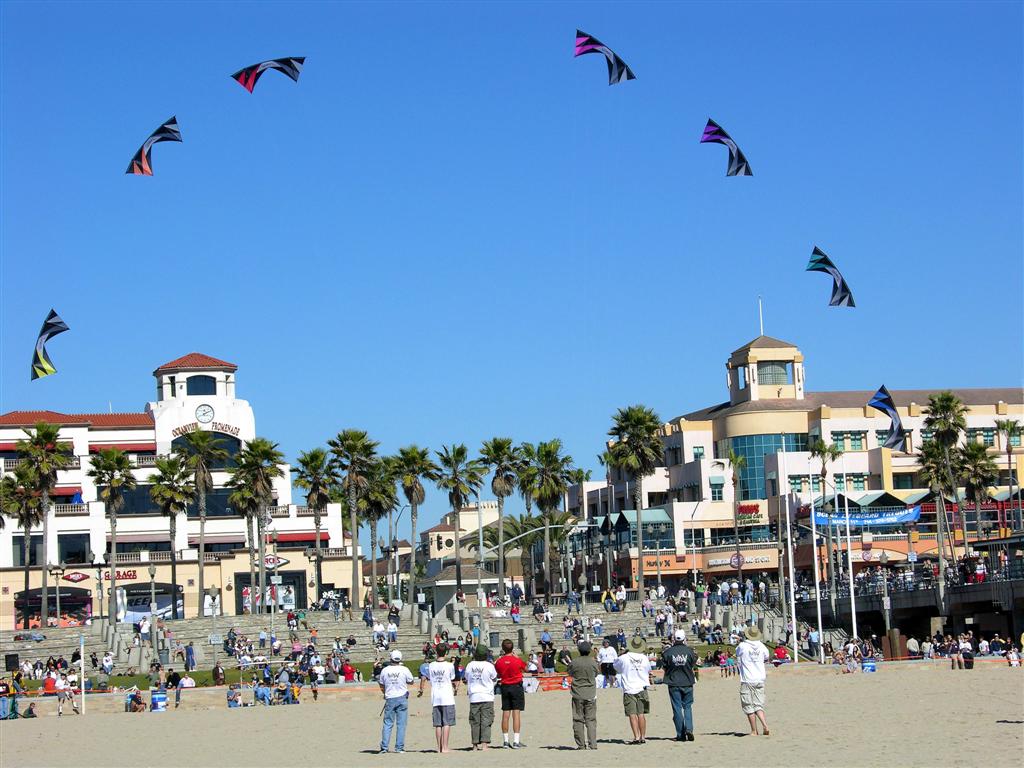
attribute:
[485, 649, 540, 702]
shirt — red 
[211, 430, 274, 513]
tree — green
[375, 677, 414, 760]
pants — light blue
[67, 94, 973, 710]
show — kite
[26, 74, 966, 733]
show — kite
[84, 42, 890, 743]
show — kite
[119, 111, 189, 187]
kite — black, pink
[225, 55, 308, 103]
kite — pink, black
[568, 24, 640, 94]
kite — black, pink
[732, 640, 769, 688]
shirt — white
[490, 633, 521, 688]
shirt — red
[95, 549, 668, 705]
stadium — wide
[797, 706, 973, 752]
ground — sandy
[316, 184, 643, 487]
sky — blue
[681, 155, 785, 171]
kite — purple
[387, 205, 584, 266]
sky — blue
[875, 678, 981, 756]
ground — sandy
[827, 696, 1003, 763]
sand — brown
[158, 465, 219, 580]
wall — white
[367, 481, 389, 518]
leaves — green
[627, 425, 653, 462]
leaves — green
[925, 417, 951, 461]
leaves — green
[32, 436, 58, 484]
leaves — green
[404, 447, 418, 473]
leaves — green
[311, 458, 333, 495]
leaves — green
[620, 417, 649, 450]
leaves — green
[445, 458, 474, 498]
leaves — green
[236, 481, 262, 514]
leaves — green